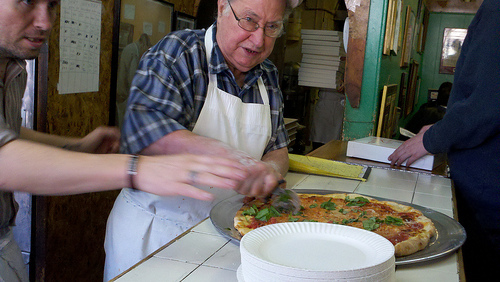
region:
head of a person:
[208, 5, 294, 85]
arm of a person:
[248, 114, 311, 201]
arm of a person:
[2, 125, 182, 200]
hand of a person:
[125, 149, 243, 204]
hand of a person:
[380, 130, 427, 177]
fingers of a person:
[196, 140, 270, 196]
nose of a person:
[245, 29, 269, 49]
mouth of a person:
[234, 48, 263, 60]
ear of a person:
[210, 3, 230, 25]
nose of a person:
[33, 5, 68, 31]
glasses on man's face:
[233, 15, 282, 34]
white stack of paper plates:
[242, 219, 397, 280]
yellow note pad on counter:
[288, 148, 371, 184]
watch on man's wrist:
[124, 156, 146, 193]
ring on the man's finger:
[186, 171, 204, 184]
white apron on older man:
[125, 39, 277, 251]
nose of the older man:
[252, 27, 266, 49]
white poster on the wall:
[63, 0, 105, 101]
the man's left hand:
[382, 123, 441, 175]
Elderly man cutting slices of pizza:
[102, 0, 302, 280]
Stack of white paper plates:
[234, 219, 399, 280]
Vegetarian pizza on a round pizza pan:
[204, 183, 468, 268]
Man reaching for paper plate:
[0, 0, 249, 280]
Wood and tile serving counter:
[107, 134, 466, 280]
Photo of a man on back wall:
[106, 2, 175, 139]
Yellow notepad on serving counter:
[277, 149, 371, 183]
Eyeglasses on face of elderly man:
[224, 0, 285, 38]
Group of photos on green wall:
[371, 0, 429, 140]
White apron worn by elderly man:
[104, 22, 274, 280]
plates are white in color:
[237, 196, 383, 280]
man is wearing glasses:
[230, 7, 285, 44]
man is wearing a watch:
[109, 145, 158, 200]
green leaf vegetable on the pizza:
[248, 205, 269, 216]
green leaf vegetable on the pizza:
[263, 201, 279, 219]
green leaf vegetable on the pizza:
[285, 210, 301, 222]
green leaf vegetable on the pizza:
[320, 195, 332, 210]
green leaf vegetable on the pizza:
[360, 210, 378, 230]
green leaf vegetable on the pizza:
[385, 206, 400, 226]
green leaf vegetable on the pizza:
[346, 190, 363, 205]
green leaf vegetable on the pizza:
[340, 208, 357, 223]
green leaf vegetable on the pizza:
[306, 200, 317, 210]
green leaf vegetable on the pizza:
[243, 205, 260, 216]